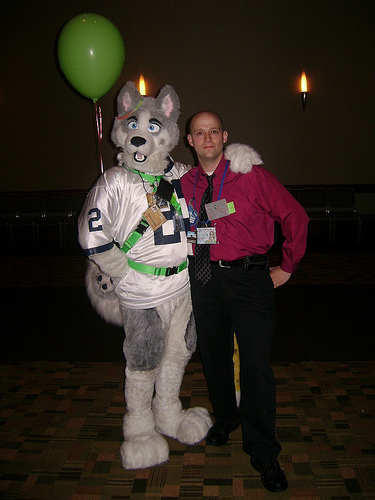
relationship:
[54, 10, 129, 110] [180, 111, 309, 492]
balloon near man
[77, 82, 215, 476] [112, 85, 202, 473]
person in costume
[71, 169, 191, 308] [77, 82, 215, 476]
jersey on person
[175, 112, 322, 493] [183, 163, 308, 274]
man in shirt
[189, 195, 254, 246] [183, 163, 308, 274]
sticker on shirt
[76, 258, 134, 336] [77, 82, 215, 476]
tail behind person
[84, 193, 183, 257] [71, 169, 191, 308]
number on jersey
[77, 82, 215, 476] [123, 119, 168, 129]
person has eyes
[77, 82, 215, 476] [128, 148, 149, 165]
person has mouth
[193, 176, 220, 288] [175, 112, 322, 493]
tie on man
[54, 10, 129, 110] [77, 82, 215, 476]
balloon near person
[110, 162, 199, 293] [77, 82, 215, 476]
straps on person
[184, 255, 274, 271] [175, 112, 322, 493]
belt on man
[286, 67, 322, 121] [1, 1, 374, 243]
light on wall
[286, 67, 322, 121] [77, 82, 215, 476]
light behind person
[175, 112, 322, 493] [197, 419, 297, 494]
man has feet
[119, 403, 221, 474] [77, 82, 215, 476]
paws on person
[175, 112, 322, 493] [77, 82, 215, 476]
man with person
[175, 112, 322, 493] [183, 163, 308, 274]
man wearing shirt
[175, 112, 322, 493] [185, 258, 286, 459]
man in pants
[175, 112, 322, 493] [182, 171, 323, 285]
man has arms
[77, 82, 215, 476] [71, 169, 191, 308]
person wearing jersey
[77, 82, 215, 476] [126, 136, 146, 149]
person has nose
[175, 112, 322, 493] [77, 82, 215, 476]
man and person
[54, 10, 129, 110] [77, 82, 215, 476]
balloon behind person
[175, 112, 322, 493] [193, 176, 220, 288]
man in tie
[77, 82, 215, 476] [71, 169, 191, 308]
person in jersey